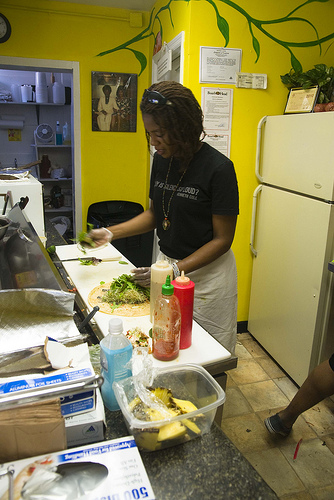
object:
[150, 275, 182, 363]
sauce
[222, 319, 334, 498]
floor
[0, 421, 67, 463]
bags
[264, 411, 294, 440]
shoe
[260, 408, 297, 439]
foot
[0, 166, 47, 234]
refrigerator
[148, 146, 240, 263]
shirt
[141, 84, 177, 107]
sunglasses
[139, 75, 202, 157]
head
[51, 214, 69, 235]
fan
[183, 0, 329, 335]
wall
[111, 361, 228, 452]
container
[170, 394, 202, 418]
pineapples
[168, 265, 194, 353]
bottle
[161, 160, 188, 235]
necklace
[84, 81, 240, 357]
woman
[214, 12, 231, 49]
leaves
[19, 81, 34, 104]
cups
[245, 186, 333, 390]
door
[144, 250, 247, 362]
apron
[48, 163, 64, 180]
water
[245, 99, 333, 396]
refrigerator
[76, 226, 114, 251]
gloves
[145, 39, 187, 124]
door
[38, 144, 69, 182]
shelf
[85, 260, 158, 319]
tortilla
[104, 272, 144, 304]
vegetables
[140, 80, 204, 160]
hair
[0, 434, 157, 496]
box